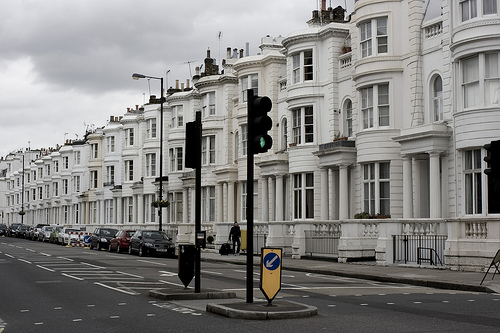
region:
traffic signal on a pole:
[238, 77, 286, 306]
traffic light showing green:
[235, 76, 302, 173]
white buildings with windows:
[341, 6, 498, 301]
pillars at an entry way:
[386, 118, 457, 257]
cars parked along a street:
[38, 211, 183, 267]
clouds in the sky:
[0, 4, 159, 131]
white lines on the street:
[39, 249, 143, 311]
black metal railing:
[386, 229, 473, 271]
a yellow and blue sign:
[248, 236, 330, 319]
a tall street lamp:
[122, 58, 173, 262]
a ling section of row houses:
[0, 0, 499, 271]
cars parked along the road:
[7, 218, 180, 258]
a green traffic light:
[244, 85, 272, 154]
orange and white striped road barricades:
[53, 222, 93, 254]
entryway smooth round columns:
[395, 142, 446, 223]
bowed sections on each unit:
[280, 37, 325, 237]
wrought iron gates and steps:
[391, 230, 441, 271]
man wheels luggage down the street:
[213, 220, 244, 256]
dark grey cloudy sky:
[11, 0, 246, 122]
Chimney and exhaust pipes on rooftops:
[182, 0, 352, 97]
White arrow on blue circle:
[264, 252, 277, 268]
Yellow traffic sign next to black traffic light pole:
[258, 243, 281, 301]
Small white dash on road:
[141, 311, 157, 318]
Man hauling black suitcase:
[215, 215, 241, 255]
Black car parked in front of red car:
[128, 221, 175, 257]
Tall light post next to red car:
[125, 70, 171, 235]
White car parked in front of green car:
[57, 227, 87, 244]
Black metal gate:
[389, 231, 449, 264]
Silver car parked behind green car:
[36, 225, 54, 238]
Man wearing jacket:
[215, 216, 246, 254]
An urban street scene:
[9, 15, 494, 321]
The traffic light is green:
[239, 80, 288, 178]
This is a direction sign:
[254, 234, 289, 314]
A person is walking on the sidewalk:
[217, 213, 244, 263]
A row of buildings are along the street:
[13, 5, 493, 258]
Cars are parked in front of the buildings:
[3, 212, 174, 258]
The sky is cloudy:
[7, 15, 112, 117]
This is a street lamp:
[122, 62, 174, 226]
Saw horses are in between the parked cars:
[56, 226, 116, 248]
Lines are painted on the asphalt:
[46, 249, 153, 308]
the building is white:
[355, 56, 477, 210]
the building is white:
[320, 1, 449, 142]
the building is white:
[322, 123, 448, 227]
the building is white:
[284, 27, 446, 224]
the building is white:
[330, 134, 482, 269]